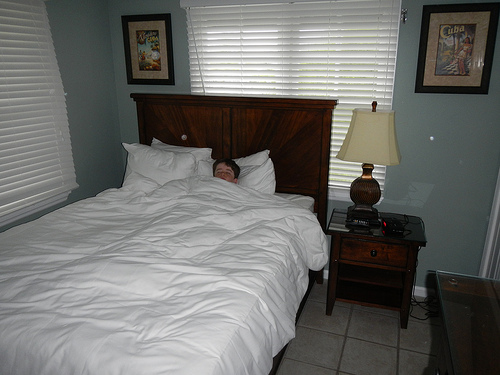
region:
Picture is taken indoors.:
[37, 27, 451, 353]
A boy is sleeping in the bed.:
[53, 91, 325, 364]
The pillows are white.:
[104, 140, 296, 207]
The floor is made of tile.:
[312, 311, 399, 373]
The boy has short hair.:
[207, 144, 256, 198]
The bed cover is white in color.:
[47, 162, 239, 348]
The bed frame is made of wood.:
[128, 86, 328, 186]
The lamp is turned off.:
[344, 107, 419, 287]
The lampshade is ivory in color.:
[336, 86, 430, 197]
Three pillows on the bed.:
[103, 130, 280, 207]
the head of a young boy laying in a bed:
[188, 148, 251, 198]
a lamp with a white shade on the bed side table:
[329, 97, 408, 224]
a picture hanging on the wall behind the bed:
[113, 10, 178, 88]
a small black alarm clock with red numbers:
[381, 211, 408, 239]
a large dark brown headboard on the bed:
[125, 83, 338, 163]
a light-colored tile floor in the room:
[303, 322, 422, 374]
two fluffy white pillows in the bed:
[121, 133, 203, 194]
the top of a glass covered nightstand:
[428, 261, 497, 370]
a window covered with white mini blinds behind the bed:
[184, 6, 403, 98]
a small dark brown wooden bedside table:
[324, 206, 425, 329]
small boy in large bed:
[96, 80, 342, 311]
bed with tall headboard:
[1, 65, 351, 370]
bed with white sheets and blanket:
[0, 76, 335, 371]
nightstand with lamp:
[325, 95, 425, 325]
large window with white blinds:
[175, 0, 396, 210]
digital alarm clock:
[370, 210, 430, 241]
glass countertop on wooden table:
[425, 258, 491, 373]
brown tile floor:
[265, 260, 435, 372]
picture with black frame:
[415, 5, 497, 103]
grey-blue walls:
[48, 3, 493, 285]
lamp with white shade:
[334, 97, 403, 212]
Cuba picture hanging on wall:
[411, 0, 496, 96]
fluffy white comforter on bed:
[46, 185, 291, 370]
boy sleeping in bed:
[204, 151, 240, 192]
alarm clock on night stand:
[379, 212, 406, 236]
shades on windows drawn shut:
[203, 12, 350, 91]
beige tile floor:
[307, 317, 407, 373]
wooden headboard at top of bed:
[125, 87, 339, 169]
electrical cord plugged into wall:
[408, 245, 428, 331]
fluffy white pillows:
[120, 132, 212, 194]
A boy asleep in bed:
[188, 144, 292, 211]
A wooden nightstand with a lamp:
[332, 159, 420, 304]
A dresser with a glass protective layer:
[421, 262, 495, 367]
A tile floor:
[311, 320, 378, 371]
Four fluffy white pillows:
[116, 135, 296, 201]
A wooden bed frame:
[125, 82, 337, 207]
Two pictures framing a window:
[115, 1, 490, 86]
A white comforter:
[81, 200, 294, 339]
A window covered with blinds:
[181, 14, 394, 89]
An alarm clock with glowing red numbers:
[373, 208, 415, 240]